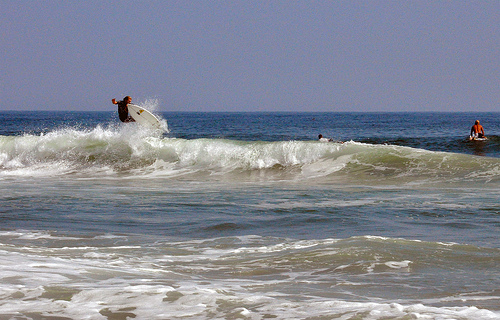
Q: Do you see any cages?
A: No, there are no cages.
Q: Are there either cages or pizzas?
A: No, there are no cages or pizzas.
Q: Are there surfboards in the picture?
A: Yes, there is a surfboard.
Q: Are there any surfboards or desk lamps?
A: Yes, there is a surfboard.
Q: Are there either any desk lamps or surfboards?
A: Yes, there is a surfboard.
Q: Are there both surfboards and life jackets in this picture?
A: No, there is a surfboard but no life jackets.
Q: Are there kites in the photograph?
A: No, there are no kites.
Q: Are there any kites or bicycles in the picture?
A: No, there are no kites or bicycles.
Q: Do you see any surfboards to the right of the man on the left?
A: Yes, there is a surfboard to the right of the man.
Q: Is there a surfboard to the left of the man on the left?
A: No, the surfboard is to the right of the man.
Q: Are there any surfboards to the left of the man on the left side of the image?
A: No, the surfboard is to the right of the man.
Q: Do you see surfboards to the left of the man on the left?
A: No, the surfboard is to the right of the man.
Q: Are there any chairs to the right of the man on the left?
A: No, there is a surfboard to the right of the man.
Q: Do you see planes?
A: No, there are no planes.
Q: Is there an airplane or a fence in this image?
A: No, there are no airplanes or fences.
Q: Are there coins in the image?
A: No, there are no coins.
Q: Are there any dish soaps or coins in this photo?
A: No, there are no coins or dish soaps.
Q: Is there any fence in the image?
A: No, there are no fences.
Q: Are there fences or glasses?
A: No, there are no fences or glasses.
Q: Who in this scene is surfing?
A: The man is surfing.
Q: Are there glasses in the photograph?
A: No, there are no glasses.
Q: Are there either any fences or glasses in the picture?
A: No, there are no glasses or fences.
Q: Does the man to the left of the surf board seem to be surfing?
A: Yes, the man is surfing.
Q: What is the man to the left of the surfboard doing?
A: The man is surfing.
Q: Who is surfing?
A: The man is surfing.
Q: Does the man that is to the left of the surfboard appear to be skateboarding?
A: No, the man is surfing.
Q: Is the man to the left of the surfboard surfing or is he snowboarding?
A: The man is surfing.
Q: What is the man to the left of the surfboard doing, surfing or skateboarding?
A: The man is surfing.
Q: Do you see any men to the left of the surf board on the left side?
A: Yes, there is a man to the left of the surf board.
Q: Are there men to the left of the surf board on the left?
A: Yes, there is a man to the left of the surf board.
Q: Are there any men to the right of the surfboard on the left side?
A: No, the man is to the left of the surfboard.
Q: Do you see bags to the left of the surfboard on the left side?
A: No, there is a man to the left of the surfboard.